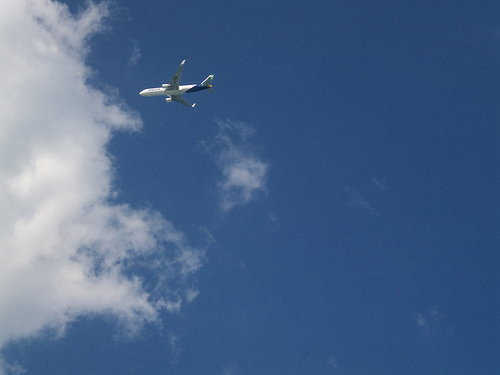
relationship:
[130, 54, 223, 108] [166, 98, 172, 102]
plane has engine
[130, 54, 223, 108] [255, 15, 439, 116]
plane against sky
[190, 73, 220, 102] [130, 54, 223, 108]
blue on plane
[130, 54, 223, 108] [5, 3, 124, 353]
plane by cloud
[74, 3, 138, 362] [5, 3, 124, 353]
edge of cloud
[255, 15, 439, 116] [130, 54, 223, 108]
sky behind plane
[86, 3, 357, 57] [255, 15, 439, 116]
part of sky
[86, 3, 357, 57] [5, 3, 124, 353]
part of cloud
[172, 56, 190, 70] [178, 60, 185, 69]
left wing left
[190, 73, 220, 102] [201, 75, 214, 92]
tail of tail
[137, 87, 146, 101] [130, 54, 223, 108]
tip of plane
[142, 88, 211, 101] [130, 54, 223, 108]
bottom of plane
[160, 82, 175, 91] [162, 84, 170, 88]
engine on engine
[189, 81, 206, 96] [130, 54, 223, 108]
blue on plane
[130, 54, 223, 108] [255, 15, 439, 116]
airplane in sky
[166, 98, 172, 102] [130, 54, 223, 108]
engine on jet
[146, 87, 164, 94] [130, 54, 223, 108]
windows on plane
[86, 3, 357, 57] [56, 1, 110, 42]
part of cloud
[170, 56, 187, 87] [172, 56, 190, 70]
wing on left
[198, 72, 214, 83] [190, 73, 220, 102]
part of tail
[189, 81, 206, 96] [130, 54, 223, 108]
blue of plane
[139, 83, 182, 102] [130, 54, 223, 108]
white of plane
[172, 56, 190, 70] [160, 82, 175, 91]
left plane engine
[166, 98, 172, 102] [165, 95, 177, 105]
engine plane engine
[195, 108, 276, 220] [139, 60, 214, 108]
cloud behind plane